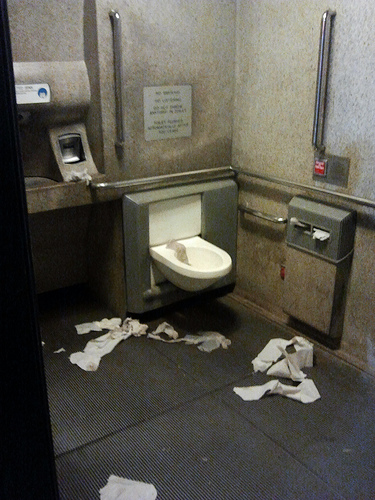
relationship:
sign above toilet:
[143, 83, 192, 140] [140, 196, 233, 296]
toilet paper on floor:
[57, 310, 323, 407] [41, 312, 361, 497]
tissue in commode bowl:
[169, 238, 188, 262] [156, 236, 227, 293]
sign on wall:
[143, 83, 192, 140] [192, 27, 286, 88]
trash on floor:
[233, 377, 320, 403] [35, 291, 369, 497]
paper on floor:
[94, 472, 160, 499] [35, 291, 369, 497]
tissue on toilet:
[169, 238, 188, 262] [148, 224, 239, 296]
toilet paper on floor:
[57, 310, 323, 407] [35, 291, 369, 497]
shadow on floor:
[168, 305, 238, 334] [35, 291, 369, 497]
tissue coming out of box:
[6, 60, 101, 132] [284, 195, 354, 263]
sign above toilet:
[138, 83, 198, 147] [129, 189, 253, 287]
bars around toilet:
[103, 5, 336, 176] [117, 187, 253, 325]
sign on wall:
[143, 83, 192, 140] [255, 73, 316, 144]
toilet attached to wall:
[125, 174, 277, 317] [10, 3, 234, 300]